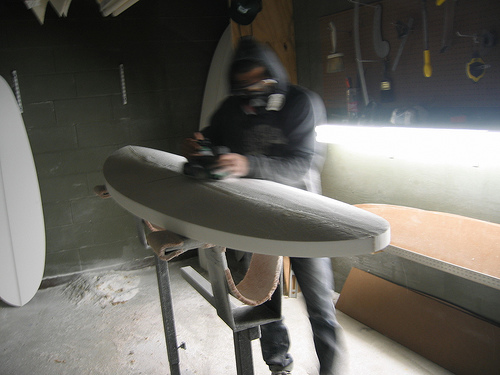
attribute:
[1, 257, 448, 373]
floor — gray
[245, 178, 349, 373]
pants — black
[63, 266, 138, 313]
dust — piled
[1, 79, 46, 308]
surfboard — white 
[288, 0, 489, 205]
wall — dark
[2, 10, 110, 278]
block wall — dark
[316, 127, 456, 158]
light — lit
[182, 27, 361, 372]
man — sanding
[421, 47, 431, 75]
handle — yellow, long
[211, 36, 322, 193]
jacket — hooded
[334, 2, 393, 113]
tool — hanging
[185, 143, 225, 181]
sander — black